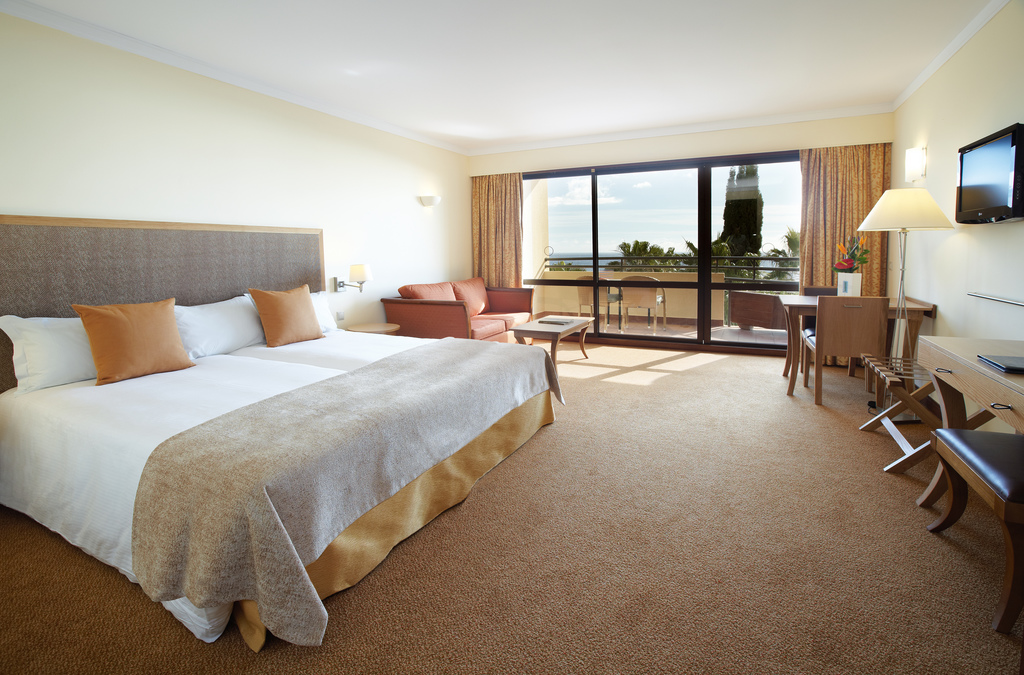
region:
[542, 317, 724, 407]
the sun is on the floor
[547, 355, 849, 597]
the carpet is tannish brown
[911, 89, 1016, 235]
the tv is on the wall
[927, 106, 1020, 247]
the tv is black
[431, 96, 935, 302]
the drapes are open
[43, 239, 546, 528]
the bed is neat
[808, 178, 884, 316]
flowers are on the table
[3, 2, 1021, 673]
interior of hotel room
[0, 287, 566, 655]
linen on top of bed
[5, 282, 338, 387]
assorted upright bed pillows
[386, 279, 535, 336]
loveseat with light reflection on cushion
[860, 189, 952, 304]
glowing shade of lamp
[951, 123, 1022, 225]
screen of flat television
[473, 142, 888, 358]
open curtains on window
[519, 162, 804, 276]
light in daytime sky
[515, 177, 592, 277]
a window on a building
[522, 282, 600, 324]
a window on a building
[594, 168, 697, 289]
a window on a building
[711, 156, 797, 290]
a window on a building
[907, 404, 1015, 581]
a chair that you sit in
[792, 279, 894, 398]
a chair that you sit in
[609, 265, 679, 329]
a chair that is outside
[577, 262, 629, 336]
a chair that is outside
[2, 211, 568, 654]
large bed in a hotel room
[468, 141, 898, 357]
sliding glass doors leading to a patio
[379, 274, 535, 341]
brown couch is against the wall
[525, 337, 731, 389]
light shining on the floor through the windows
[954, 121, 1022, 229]
television hanging on the wall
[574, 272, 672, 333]
patio chairs on the deck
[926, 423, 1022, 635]
black leather and wood bench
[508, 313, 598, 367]
coffee table in front of a couch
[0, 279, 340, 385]
The pillows are white and brown.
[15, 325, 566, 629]
The blankets are white gray and brown.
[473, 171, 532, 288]
The curtain is brown.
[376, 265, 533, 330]
The couch is red.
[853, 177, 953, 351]
The lamp is turned on.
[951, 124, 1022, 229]
The television is hanging on the wall.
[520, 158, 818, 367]
The glass doors open up to a balcony outside.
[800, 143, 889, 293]
The curtain is brown.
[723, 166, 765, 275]
tall large green bush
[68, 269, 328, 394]
Two brown square pillows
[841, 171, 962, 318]
White lampshade on a lamp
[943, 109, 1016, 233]
Flat screen TV hanging on the wall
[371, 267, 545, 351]
A red colored couch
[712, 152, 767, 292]
A tall green tree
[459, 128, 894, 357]
Brown curtains over a large window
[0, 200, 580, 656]
A neatly made up bed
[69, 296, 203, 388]
square brown cloth pillow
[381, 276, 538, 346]
long red leather couch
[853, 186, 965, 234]
large white round lamp shade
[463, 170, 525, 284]
long tall brown drapes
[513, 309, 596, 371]
small square wooden table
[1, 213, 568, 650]
large wide white bed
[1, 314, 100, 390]
large square white pillow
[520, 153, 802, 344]
large wide glass window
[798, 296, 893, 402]
small wooden short chair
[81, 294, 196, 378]
the orange pillow on the bed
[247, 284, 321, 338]
the orange pillow on the bed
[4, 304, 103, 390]
the white pillow on the bed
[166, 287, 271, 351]
the white pillow on the bed